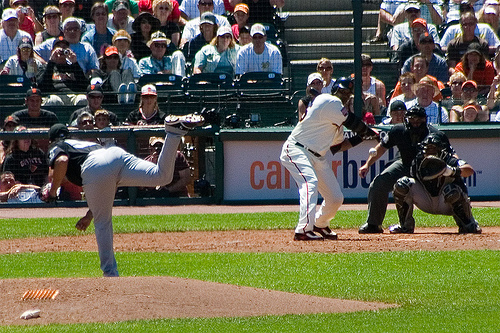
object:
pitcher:
[42, 112, 206, 275]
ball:
[368, 147, 378, 157]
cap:
[249, 23, 266, 37]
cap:
[141, 83, 158, 95]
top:
[203, 52, 237, 65]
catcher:
[388, 131, 480, 235]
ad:
[221, 136, 498, 201]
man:
[232, 22, 283, 77]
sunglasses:
[253, 35, 269, 39]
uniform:
[276, 94, 355, 236]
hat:
[412, 74, 440, 88]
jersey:
[45, 134, 90, 186]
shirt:
[287, 93, 349, 157]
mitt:
[404, 156, 456, 194]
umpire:
[359, 87, 448, 234]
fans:
[9, 1, 127, 77]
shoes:
[294, 231, 325, 241]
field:
[128, 257, 498, 320]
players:
[277, 75, 364, 240]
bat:
[353, 97, 398, 155]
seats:
[183, 72, 236, 97]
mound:
[0, 276, 419, 325]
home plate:
[383, 233, 488, 250]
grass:
[222, 256, 404, 281]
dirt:
[340, 235, 437, 252]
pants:
[280, 142, 342, 232]